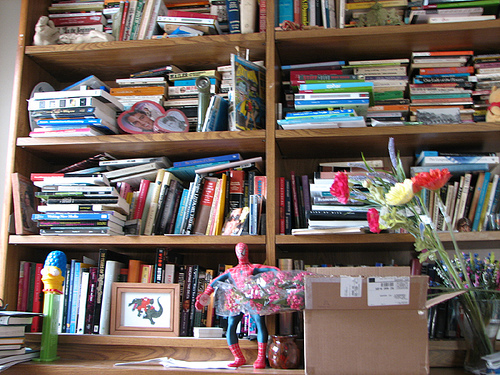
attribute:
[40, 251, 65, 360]
character — for pez candy, dispenser, named marge, a simpson, from a cartoon, pez candy holder, a dispenser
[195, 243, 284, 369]
man — a figure, made of plastic, spider character, standing up, a figurine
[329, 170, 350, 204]
flower — pink, bagged, red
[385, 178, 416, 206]
flower — yellow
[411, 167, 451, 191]
flower — pink, bagged, red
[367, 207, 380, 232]
flower — pink, bagged, red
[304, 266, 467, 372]
box — cardboard, open, brown, shade of brown, small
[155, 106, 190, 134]
frame — heart shaped, a heart, shaped, for picture, heart-shaped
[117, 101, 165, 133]
frame — heart shaped, a heart, shaped, for picture, heart-shaped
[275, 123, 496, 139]
shelf — brown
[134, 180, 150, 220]
book — red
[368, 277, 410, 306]
sticker — for packaging, white, for mailing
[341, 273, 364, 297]
sticker — for packaging, white, for mailing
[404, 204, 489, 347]
stem — green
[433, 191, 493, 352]
stem — green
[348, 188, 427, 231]
stem — green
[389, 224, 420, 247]
stem — green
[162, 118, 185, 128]
image — of elvis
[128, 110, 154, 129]
image — of elvis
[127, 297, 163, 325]
image — framed, a crocodile, an alligator, a picture, small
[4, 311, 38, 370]
pile — composed of books, on their sides, stacked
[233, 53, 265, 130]
book — comic style, about robin, about batman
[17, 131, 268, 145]
shelf — stacked with books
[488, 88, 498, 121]
figurine — showing one side, pooh bear, named winnie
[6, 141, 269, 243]
shelf — stacked, in disarray, holding books, full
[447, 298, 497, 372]
vase — clear, glass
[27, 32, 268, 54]
shelf — stacked with books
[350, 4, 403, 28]
figurine — gray, a rabbit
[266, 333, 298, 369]
vase — brown, red, small